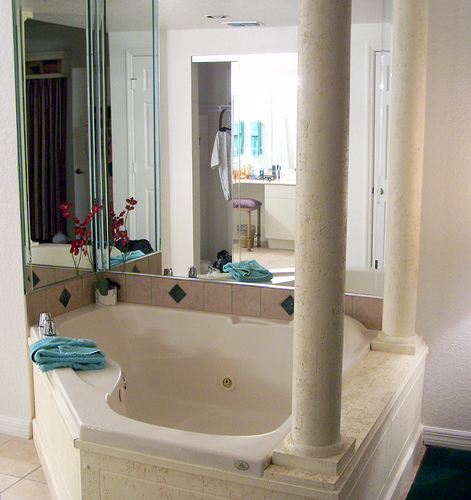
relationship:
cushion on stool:
[231, 193, 263, 209] [231, 190, 263, 251]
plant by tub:
[55, 201, 106, 280] [29, 303, 425, 496]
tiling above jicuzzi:
[22, 269, 383, 331] [28, 301, 366, 493]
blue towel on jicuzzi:
[27, 335, 105, 374] [28, 301, 366, 493]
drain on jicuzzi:
[207, 365, 237, 393] [28, 298, 420, 496]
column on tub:
[271, 1, 369, 473] [29, 303, 425, 496]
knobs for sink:
[38, 295, 64, 353] [211, 166, 295, 183]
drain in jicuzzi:
[222, 375, 235, 391] [28, 301, 366, 493]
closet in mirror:
[183, 52, 237, 278] [193, 56, 309, 287]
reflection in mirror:
[23, 22, 363, 302] [75, 10, 355, 310]